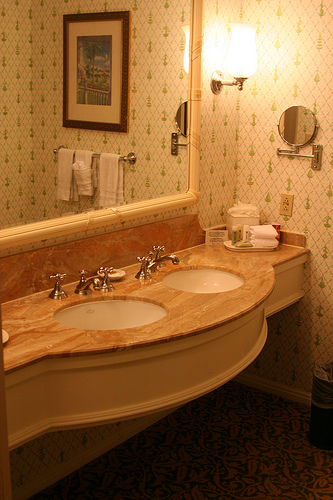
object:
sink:
[50, 293, 170, 331]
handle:
[48, 268, 71, 302]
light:
[225, 23, 259, 80]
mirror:
[0, 0, 205, 251]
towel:
[96, 150, 125, 210]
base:
[4, 254, 310, 456]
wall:
[201, 3, 332, 400]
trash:
[308, 361, 332, 445]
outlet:
[278, 190, 294, 217]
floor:
[28, 378, 331, 498]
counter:
[3, 244, 313, 373]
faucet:
[149, 246, 180, 276]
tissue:
[227, 199, 262, 238]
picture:
[61, 10, 130, 133]